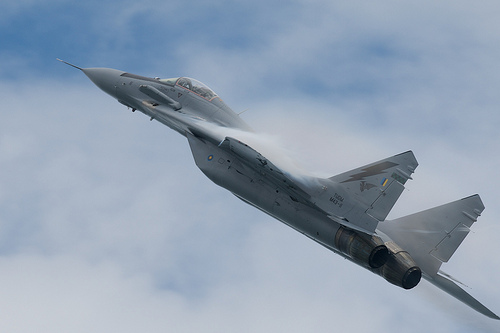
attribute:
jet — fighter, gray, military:
[53, 56, 498, 322]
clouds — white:
[41, 174, 163, 254]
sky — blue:
[1, 2, 419, 307]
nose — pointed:
[51, 53, 94, 76]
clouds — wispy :
[25, 144, 212, 286]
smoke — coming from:
[198, 115, 318, 177]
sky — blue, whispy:
[31, 19, 443, 330]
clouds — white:
[17, 121, 167, 326]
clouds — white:
[259, 46, 384, 113]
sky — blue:
[20, 169, 170, 329]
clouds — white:
[39, 180, 237, 304]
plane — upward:
[54, 51, 499, 323]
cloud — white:
[262, 0, 498, 117]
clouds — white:
[3, 6, 495, 331]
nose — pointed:
[48, 50, 123, 98]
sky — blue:
[7, 117, 232, 292]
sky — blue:
[5, 183, 248, 323]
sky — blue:
[1, 205, 297, 315]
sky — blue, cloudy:
[0, 3, 498, 331]